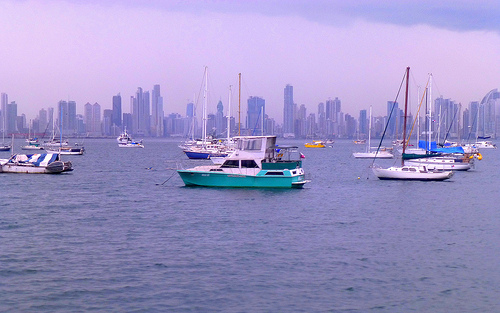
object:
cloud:
[138, 0, 493, 52]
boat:
[0, 148, 74, 174]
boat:
[352, 106, 394, 160]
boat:
[183, 66, 234, 159]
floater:
[0, 146, 74, 175]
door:
[280, 148, 289, 162]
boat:
[117, 126, 145, 148]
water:
[4, 172, 69, 192]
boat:
[45, 108, 85, 155]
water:
[206, 224, 275, 260]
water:
[182, 277, 272, 308]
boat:
[369, 66, 454, 181]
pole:
[400, 66, 410, 165]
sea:
[1, 193, 497, 311]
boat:
[176, 66, 313, 191]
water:
[62, 243, 153, 300]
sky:
[326, 45, 393, 72]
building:
[281, 83, 295, 136]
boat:
[403, 73, 475, 171]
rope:
[160, 171, 175, 185]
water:
[81, 188, 138, 209]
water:
[288, 259, 330, 272]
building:
[131, 83, 163, 136]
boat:
[304, 140, 326, 149]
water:
[329, 169, 353, 187]